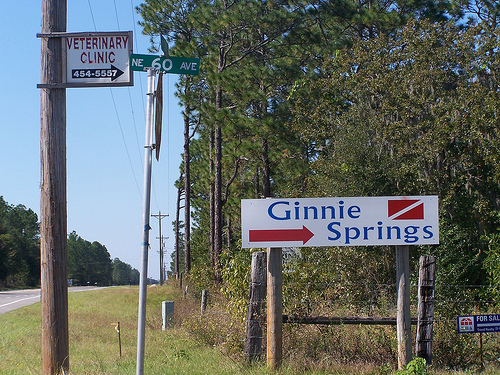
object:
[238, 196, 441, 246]
sign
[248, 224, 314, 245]
arrow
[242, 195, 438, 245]
white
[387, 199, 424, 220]
block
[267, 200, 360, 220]
writing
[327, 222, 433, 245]
writing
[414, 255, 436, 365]
post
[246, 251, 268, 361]
wood post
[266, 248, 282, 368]
wood post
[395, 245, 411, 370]
wood post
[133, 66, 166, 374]
post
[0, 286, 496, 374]
ground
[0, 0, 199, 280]
sky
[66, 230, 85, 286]
trees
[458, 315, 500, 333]
sale sign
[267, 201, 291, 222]
g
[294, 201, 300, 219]
i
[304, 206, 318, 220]
n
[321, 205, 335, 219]
n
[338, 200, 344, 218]
i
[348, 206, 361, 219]
e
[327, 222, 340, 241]
s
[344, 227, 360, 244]
p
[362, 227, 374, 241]
r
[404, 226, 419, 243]
g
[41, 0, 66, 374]
pole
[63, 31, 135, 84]
posting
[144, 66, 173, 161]
stop sign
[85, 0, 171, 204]
wire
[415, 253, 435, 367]
pole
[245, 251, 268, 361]
pole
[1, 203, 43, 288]
trees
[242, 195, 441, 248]
post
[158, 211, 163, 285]
pole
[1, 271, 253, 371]
grass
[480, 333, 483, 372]
pole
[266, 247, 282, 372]
pole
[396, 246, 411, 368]
pole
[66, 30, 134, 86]
sign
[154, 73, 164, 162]
sign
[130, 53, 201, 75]
sign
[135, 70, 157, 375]
pole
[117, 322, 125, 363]
stick